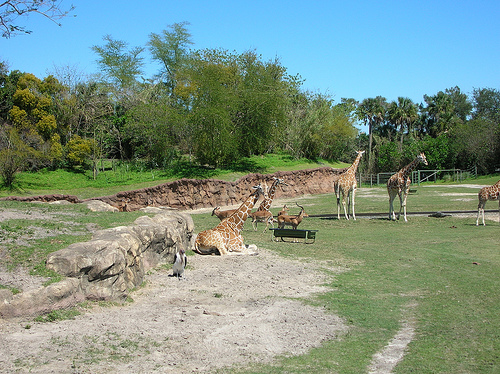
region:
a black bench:
[266, 221, 320, 243]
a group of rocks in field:
[14, 211, 199, 306]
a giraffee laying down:
[196, 176, 267, 268]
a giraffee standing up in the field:
[328, 144, 369, 224]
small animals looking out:
[255, 202, 313, 229]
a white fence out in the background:
[368, 161, 491, 183]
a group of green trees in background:
[0, 17, 499, 177]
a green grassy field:
[221, 222, 498, 367]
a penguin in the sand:
[171, 242, 188, 277]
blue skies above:
[2, 0, 499, 96]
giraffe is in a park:
[327, 145, 368, 221]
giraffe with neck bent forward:
[383, 147, 425, 217]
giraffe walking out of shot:
[465, 180, 499, 207]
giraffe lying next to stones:
[199, 187, 265, 269]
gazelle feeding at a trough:
[270, 205, 311, 242]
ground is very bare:
[49, 252, 334, 362]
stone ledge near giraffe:
[58, 204, 198, 296]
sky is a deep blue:
[333, 10, 495, 95]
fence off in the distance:
[361, 165, 467, 190]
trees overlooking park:
[37, 67, 345, 201]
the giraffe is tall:
[210, 123, 410, 215]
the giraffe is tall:
[265, 47, 444, 256]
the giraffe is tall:
[297, 110, 362, 238]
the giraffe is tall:
[328, 59, 360, 302]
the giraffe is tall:
[305, 117, 389, 324]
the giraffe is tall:
[318, 183, 418, 373]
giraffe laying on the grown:
[184, 179, 283, 258]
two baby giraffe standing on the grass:
[332, 142, 437, 224]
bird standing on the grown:
[165, 233, 197, 289]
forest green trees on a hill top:
[72, 34, 350, 205]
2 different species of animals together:
[260, 172, 332, 241]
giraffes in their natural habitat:
[330, 129, 498, 235]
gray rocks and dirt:
[54, 237, 215, 334]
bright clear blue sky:
[310, 9, 482, 78]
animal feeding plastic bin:
[265, 222, 329, 257]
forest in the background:
[8, 57, 348, 258]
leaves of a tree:
[228, 92, 235, 104]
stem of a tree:
[223, 157, 233, 164]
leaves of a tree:
[220, 117, 237, 131]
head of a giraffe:
[420, 151, 427, 163]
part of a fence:
[460, 155, 470, 175]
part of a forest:
[456, 108, 466, 109]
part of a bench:
[281, 216, 304, 229]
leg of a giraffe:
[404, 192, 406, 198]